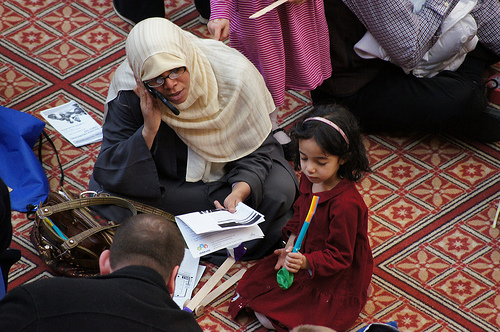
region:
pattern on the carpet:
[412, 175, 454, 204]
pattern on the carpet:
[382, 203, 420, 224]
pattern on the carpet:
[439, 233, 474, 253]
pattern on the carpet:
[408, 253, 438, 275]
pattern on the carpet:
[443, 277, 471, 296]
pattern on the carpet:
[457, 164, 482, 190]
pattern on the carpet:
[385, 161, 422, 183]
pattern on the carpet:
[420, 143, 449, 164]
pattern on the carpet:
[366, 144, 386, 164]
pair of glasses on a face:
[140, 62, 189, 98]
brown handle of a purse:
[36, 190, 143, 255]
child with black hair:
[216, 96, 393, 330]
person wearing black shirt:
[0, 198, 217, 330]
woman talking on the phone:
[80, 15, 302, 242]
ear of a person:
[167, 263, 182, 293]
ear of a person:
[96, 246, 115, 277]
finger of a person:
[211, 23, 222, 41]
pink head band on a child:
[300, 114, 351, 148]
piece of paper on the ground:
[38, 86, 114, 151]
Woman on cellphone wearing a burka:
[89, 5, 291, 167]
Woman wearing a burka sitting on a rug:
[92, 17, 299, 290]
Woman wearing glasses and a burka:
[83, 13, 287, 223]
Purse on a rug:
[6, 137, 122, 284]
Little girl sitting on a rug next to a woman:
[144, 22, 410, 327]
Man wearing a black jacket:
[11, 174, 218, 329]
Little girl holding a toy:
[246, 84, 383, 308]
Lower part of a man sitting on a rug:
[323, 0, 498, 149]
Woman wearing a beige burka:
[71, 0, 340, 218]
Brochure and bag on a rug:
[3, 15, 109, 204]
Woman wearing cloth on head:
[111, 23, 293, 158]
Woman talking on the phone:
[112, 84, 212, 139]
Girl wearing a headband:
[266, 91, 375, 146]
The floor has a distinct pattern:
[397, 143, 407, 175]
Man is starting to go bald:
[86, 195, 189, 257]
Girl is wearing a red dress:
[275, 179, 366, 319]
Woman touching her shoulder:
[193, 13, 280, 75]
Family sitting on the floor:
[59, 30, 418, 328]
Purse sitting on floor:
[24, 181, 171, 301]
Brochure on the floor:
[34, 86, 111, 161]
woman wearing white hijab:
[66, 9, 291, 176]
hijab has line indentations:
[102, 8, 276, 157]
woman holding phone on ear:
[126, 61, 184, 118]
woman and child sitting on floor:
[63, 30, 410, 327]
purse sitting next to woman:
[16, 154, 174, 304]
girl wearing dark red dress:
[228, 172, 393, 327]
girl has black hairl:
[284, 97, 372, 179]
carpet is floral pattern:
[374, 158, 494, 325]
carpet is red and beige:
[378, 158, 496, 328]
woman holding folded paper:
[160, 192, 272, 274]